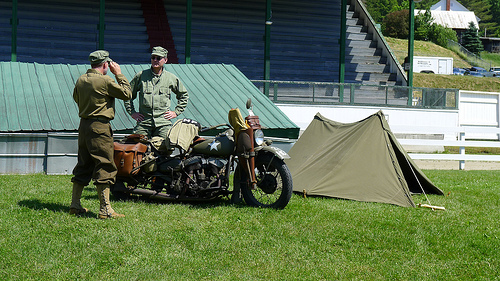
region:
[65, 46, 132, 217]
A soldier saluting another soldier.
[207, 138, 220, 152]
A star on a motorcycle tank.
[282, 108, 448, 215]
A brown tent.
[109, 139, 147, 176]
A leather bag on the side of a motorcycle.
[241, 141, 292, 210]
The front wheel of a motorcycle.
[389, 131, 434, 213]
Rope coming off the front of a tent.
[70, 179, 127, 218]
Light brown boots on a soldier.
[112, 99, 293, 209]
A motorcycle with a star on the tank.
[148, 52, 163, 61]
Black sunglasses on a man standing with his hands on his hips.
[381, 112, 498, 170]
White fence to the right of the tent.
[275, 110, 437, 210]
brown tent set up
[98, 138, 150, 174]
brown leather motorcycle bag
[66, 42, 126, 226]
man standing in army gear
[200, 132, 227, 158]
a white star painted on the bike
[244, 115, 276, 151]
a headlight on the motorcycle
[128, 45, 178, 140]
man in sunglasses and an army uniform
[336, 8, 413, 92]
a staircase on the side of the building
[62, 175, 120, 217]
tan army boots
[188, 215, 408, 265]
healthy grass on the ground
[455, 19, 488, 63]
tree outside of a house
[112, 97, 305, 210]
the old-fashioned green motorcycle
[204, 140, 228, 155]
the white star on the motorcycle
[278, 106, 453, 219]
the green army tent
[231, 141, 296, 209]
the front wheel of the motorcycle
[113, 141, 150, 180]
the brown leather side bag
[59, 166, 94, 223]
the left boot of the soldier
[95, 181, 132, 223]
the right boot of the soldier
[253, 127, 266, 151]
the headlight of the motorcycle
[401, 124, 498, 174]
the low white fence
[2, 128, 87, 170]
low metal fence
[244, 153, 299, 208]
wheel of the motrcycle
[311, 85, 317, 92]
part of the stair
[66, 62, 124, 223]
green clothes on the man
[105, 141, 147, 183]
a leather bag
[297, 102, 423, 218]
GREEN TENT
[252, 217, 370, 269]
nice green grass on the ground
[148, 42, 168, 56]
green hat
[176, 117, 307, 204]
motorcycle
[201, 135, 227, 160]
a white star on the bike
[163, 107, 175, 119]
the mans hand is resting on his hip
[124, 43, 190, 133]
A man holding his waist.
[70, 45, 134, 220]
A man saluting while standing.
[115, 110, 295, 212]
A parked motorcycle in a field.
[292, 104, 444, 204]
A camping tent in the field.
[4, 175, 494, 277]
Green grass in the field.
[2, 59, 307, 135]
Green top of a roof.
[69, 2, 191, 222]
Two people chatting together.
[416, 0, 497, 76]
A house in the background.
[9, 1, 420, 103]
Green posts supporting the roof top.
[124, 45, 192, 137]
A man wearing sunglasses on his face.